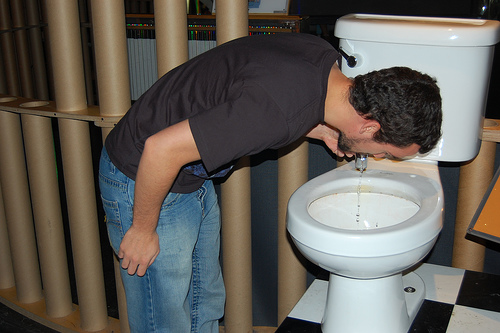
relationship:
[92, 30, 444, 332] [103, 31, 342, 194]
man in t-shirt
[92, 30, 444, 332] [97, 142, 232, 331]
man in jeans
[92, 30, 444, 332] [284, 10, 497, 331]
man looking in a toilet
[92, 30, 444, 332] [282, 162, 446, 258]
man looking in a toilet bowl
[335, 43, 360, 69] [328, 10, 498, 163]
handle on toilet tank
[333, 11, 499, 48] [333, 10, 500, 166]
top on tank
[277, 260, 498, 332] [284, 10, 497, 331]
tiles under toilet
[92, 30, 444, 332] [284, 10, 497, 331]
man inspecting toilet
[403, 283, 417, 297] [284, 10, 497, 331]
bolt on bottom side of toilet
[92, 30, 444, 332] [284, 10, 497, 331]
man looking at toilet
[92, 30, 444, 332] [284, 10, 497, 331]
man vomiting in toilet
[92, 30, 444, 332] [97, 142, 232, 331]
man wearing jeans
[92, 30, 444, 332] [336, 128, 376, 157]
man with a beard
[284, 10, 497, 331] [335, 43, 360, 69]
toilet has handle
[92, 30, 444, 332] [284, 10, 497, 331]
man leaning over toilet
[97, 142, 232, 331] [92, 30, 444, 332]
jeans on man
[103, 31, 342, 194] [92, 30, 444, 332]
t-shirt on man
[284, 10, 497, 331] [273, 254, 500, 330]
toilet on a platform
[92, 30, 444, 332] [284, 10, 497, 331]
man spitting into toilet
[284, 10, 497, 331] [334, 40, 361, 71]
toilet has a lever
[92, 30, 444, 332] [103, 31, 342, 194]
man wearing t-shirt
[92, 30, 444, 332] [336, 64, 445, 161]
man has head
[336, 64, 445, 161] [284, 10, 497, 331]
head over toilet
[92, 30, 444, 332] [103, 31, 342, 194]
man wearing a t-shirt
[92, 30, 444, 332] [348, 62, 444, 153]
man has hair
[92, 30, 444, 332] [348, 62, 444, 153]
man with hair